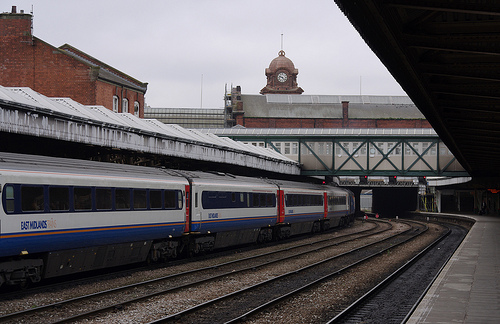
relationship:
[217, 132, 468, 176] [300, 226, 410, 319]
bridge over tracks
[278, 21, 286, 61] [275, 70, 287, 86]
metal pole on top of clock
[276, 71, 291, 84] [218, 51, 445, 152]
clock on building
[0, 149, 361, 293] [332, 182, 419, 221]
train went through tunnel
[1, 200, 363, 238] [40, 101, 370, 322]
stripe on train